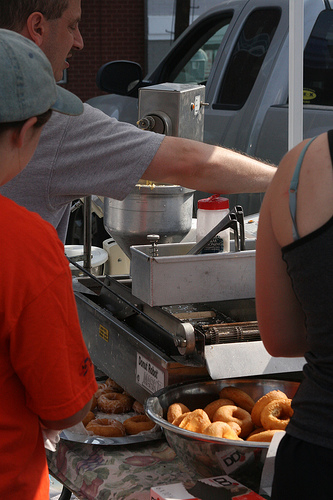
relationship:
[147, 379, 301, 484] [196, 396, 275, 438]
bowl full of donuts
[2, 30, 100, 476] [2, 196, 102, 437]
person wearing a shirt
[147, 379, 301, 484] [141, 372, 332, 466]
bowl full of donuts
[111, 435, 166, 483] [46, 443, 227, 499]
patter on tablecloth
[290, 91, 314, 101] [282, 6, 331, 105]
sticker on window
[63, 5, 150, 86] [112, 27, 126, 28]
brick building with cement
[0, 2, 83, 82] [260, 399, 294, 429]
man making fried doughnuts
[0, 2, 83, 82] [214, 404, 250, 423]
man making fried doughnuts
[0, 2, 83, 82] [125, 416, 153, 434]
man making fried doughnuts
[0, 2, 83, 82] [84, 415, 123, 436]
man making fried doughnut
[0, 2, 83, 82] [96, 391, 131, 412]
man making fried doughnut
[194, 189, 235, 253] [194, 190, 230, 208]
bottle with red lid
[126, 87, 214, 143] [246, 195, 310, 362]
mixer behind arm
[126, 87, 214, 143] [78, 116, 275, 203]
mixer behind arm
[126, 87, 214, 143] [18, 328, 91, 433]
mixer behind arm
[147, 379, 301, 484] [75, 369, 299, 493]
bowl on table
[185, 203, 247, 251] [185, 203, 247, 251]
handles for handles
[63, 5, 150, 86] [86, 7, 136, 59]
brick building has part